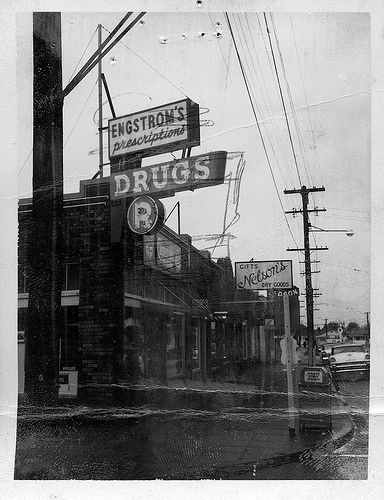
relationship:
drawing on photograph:
[182, 151, 254, 250] [1, 0, 383, 499]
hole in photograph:
[154, 37, 173, 47] [1, 0, 383, 499]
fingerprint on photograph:
[157, 418, 215, 477] [1, 0, 383, 499]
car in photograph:
[330, 343, 369, 379] [1, 0, 383, 499]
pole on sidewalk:
[284, 186, 326, 362] [19, 355, 356, 479]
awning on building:
[144, 298, 213, 317] [22, 176, 204, 411]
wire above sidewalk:
[221, 15, 302, 247] [19, 355, 356, 479]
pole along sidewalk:
[284, 186, 326, 362] [19, 355, 356, 479]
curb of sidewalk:
[177, 424, 339, 477] [19, 355, 356, 479]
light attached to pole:
[344, 231, 358, 241] [284, 186, 326, 362]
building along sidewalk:
[22, 176, 204, 411] [19, 355, 356, 479]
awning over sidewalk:
[144, 298, 213, 317] [19, 355, 356, 479]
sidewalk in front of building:
[19, 355, 356, 479] [22, 176, 204, 411]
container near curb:
[301, 363, 334, 435] [177, 424, 339, 477]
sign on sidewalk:
[237, 262, 295, 289] [19, 355, 356, 479]